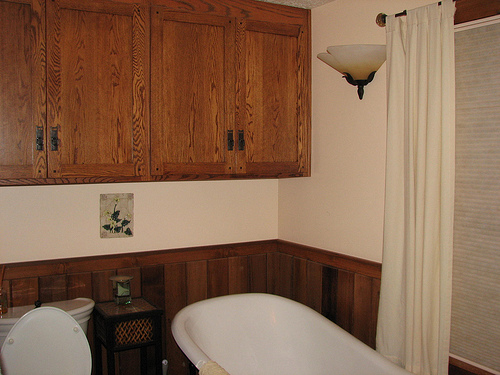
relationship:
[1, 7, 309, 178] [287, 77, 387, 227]
cavinets on wall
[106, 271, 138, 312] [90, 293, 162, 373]
candle on a stand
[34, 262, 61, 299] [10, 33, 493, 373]
paneling in a bathroom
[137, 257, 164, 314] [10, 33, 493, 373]
paneling in a bathroom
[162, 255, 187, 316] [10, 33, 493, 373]
paneling in a bathroom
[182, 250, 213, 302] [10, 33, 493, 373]
paneling in a bathroom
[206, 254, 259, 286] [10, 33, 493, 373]
paneling in a bathroom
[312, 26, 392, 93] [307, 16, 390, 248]
light mounted on wall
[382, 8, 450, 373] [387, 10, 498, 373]
curtain over a window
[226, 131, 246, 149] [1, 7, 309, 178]
black handles on cavinets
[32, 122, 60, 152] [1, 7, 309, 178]
black handles on cavinets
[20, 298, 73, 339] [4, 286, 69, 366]
lid on a toilet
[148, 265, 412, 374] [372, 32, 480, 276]
bathtub next to window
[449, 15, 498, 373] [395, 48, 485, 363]
shade over window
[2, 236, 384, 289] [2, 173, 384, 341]
paneling on wall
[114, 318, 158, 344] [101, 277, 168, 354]
pattern woven on table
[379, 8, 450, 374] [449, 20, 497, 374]
curtain on window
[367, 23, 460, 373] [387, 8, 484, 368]
blinds on window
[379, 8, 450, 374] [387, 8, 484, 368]
curtain on window